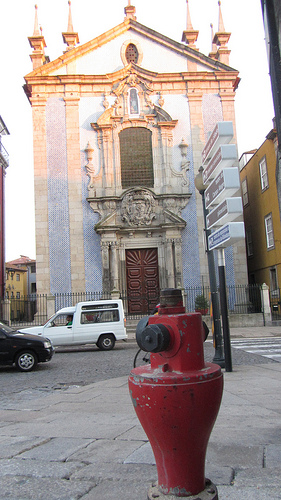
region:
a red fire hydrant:
[126, 287, 221, 492]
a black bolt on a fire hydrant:
[135, 323, 173, 358]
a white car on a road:
[26, 297, 125, 350]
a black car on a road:
[0, 315, 51, 380]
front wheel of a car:
[14, 352, 34, 375]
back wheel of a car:
[97, 334, 118, 354]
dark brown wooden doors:
[126, 246, 160, 314]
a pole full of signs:
[201, 116, 239, 371]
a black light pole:
[195, 163, 225, 362]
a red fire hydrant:
[124, 286, 225, 495]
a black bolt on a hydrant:
[141, 323, 168, 355]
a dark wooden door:
[126, 248, 158, 313]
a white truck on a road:
[18, 296, 128, 353]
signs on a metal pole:
[203, 119, 245, 364]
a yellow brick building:
[244, 128, 278, 305]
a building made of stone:
[28, 0, 236, 292]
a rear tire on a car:
[101, 334, 114, 354]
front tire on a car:
[17, 354, 33, 367]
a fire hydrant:
[133, 286, 230, 493]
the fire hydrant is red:
[114, 302, 242, 491]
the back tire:
[97, 335, 117, 347]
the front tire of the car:
[18, 349, 36, 370]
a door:
[129, 261, 157, 291]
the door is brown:
[129, 266, 161, 289]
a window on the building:
[263, 219, 276, 251]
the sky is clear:
[8, 223, 27, 245]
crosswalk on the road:
[218, 330, 279, 367]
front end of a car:
[0, 314, 51, 371]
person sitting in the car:
[61, 312, 76, 328]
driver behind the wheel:
[50, 314, 74, 326]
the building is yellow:
[1, 252, 29, 317]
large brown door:
[122, 247, 164, 314]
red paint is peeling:
[130, 368, 157, 383]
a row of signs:
[196, 125, 252, 249]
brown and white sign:
[201, 198, 242, 231]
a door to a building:
[118, 247, 166, 316]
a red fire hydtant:
[120, 288, 224, 494]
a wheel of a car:
[95, 333, 117, 350]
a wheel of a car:
[14, 348, 36, 371]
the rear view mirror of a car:
[45, 320, 55, 328]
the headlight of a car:
[41, 339, 51, 350]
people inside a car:
[57, 312, 75, 327]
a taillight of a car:
[120, 315, 130, 323]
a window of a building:
[14, 272, 22, 281]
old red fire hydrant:
[132, 284, 219, 498]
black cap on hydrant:
[142, 325, 169, 351]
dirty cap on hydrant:
[158, 287, 185, 311]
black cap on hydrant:
[135, 317, 147, 353]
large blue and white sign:
[206, 225, 246, 247]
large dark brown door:
[124, 248, 160, 314]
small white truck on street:
[17, 299, 126, 345]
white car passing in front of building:
[20, 295, 121, 342]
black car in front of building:
[0, 315, 71, 369]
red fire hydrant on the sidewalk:
[117, 282, 244, 499]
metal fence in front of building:
[185, 281, 259, 318]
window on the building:
[262, 212, 278, 251]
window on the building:
[254, 153, 269, 197]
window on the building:
[128, 83, 139, 115]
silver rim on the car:
[18, 348, 34, 368]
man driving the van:
[60, 310, 75, 327]